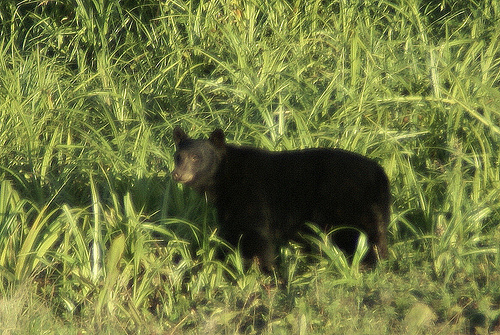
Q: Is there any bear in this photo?
A: Yes, there is a bear.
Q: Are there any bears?
A: Yes, there is a bear.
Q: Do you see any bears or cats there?
A: Yes, there is a bear.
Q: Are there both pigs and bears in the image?
A: No, there is a bear but no pigs.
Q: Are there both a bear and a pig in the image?
A: No, there is a bear but no pigs.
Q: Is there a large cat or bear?
A: Yes, there is a large bear.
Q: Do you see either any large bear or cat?
A: Yes, there is a large bear.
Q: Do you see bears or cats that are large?
A: Yes, the bear is large.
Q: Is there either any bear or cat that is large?
A: Yes, the bear is large.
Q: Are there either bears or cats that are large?
A: Yes, the bear is large.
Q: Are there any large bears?
A: Yes, there is a large bear.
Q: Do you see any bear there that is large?
A: Yes, there is a large bear.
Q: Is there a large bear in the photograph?
A: Yes, there is a large bear.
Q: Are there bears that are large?
A: Yes, there is a bear that is large.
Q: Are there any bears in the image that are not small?
A: Yes, there is a large bear.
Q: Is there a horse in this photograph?
A: No, there are no horses.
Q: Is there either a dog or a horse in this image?
A: No, there are no horses or dogs.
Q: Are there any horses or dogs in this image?
A: No, there are no horses or dogs.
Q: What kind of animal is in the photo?
A: The animal is a bear.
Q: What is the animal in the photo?
A: The animal is a bear.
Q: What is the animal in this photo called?
A: The animal is a bear.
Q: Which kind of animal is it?
A: The animal is a bear.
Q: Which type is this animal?
A: This is a bear.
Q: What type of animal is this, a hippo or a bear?
A: This is a bear.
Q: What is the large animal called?
A: The animal is a bear.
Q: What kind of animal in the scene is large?
A: The animal is a bear.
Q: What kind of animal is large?
A: The animal is a bear.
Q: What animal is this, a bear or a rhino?
A: This is a bear.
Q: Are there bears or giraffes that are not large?
A: No, there is a bear but it is large.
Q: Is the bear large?
A: Yes, the bear is large.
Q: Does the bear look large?
A: Yes, the bear is large.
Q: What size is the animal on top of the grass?
A: The bear is large.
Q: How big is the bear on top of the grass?
A: The bear is large.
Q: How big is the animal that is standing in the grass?
A: The bear is large.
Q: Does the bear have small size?
A: No, the bear is large.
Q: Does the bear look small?
A: No, the bear is large.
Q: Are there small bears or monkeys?
A: No, there is a bear but it is large.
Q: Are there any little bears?
A: No, there is a bear but it is large.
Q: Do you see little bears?
A: No, there is a bear but it is large.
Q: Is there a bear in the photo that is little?
A: No, there is a bear but it is large.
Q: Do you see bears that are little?
A: No, there is a bear but it is large.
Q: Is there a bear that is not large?
A: No, there is a bear but it is large.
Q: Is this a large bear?
A: Yes, this is a large bear.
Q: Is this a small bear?
A: No, this is a large bear.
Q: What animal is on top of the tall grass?
A: The bear is on top of the grass.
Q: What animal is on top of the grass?
A: The bear is on top of the grass.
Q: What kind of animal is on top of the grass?
A: The animal is a bear.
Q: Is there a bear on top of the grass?
A: Yes, there is a bear on top of the grass.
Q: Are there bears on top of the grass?
A: Yes, there is a bear on top of the grass.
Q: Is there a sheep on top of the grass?
A: No, there is a bear on top of the grass.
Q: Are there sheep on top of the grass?
A: No, there is a bear on top of the grass.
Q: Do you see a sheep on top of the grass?
A: No, there is a bear on top of the grass.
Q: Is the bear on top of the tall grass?
A: Yes, the bear is on top of the grass.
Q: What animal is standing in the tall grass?
A: The bear is standing in the grass.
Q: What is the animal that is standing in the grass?
A: The animal is a bear.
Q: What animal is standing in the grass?
A: The animal is a bear.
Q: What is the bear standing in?
A: The bear is standing in the grass.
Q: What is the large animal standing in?
A: The bear is standing in the grass.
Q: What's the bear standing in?
A: The bear is standing in the grass.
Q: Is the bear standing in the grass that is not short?
A: Yes, the bear is standing in the grass.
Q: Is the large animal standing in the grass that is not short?
A: Yes, the bear is standing in the grass.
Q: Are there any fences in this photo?
A: No, there are no fences.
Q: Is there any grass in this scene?
A: Yes, there is grass.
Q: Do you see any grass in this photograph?
A: Yes, there is grass.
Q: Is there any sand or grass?
A: Yes, there is grass.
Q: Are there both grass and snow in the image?
A: No, there is grass but no snow.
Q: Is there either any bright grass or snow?
A: Yes, there is bright grass.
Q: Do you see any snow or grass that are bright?
A: Yes, the grass is bright.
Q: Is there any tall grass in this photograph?
A: Yes, there is tall grass.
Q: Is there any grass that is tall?
A: Yes, there is grass that is tall.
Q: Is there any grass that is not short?
A: Yes, there is tall grass.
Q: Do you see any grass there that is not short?
A: Yes, there is tall grass.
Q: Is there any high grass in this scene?
A: Yes, there is high grass.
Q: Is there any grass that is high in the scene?
A: Yes, there is high grass.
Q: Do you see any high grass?
A: Yes, there is high grass.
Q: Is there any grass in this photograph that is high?
A: Yes, there is grass that is high.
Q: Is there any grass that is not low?
A: Yes, there is high grass.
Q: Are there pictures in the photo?
A: No, there are no pictures.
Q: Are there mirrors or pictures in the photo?
A: No, there are no pictures or mirrors.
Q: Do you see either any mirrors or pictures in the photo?
A: No, there are no pictures or mirrors.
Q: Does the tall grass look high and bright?
A: Yes, the grass is high and bright.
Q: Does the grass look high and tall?
A: Yes, the grass is high and tall.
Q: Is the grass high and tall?
A: Yes, the grass is high and tall.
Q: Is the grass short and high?
A: No, the grass is high but tall.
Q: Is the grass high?
A: Yes, the grass is high.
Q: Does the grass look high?
A: Yes, the grass is high.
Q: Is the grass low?
A: No, the grass is high.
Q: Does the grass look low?
A: No, the grass is high.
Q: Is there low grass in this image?
A: No, there is grass but it is high.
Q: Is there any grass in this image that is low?
A: No, there is grass but it is high.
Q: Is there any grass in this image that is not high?
A: No, there is grass but it is high.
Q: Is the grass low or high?
A: The grass is high.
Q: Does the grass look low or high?
A: The grass is high.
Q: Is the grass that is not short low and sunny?
A: No, the grass is sunny but high.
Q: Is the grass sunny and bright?
A: Yes, the grass is sunny and bright.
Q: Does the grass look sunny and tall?
A: Yes, the grass is sunny and tall.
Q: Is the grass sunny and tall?
A: Yes, the grass is sunny and tall.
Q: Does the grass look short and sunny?
A: No, the grass is sunny but tall.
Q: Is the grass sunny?
A: Yes, the grass is sunny.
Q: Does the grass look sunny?
A: Yes, the grass is sunny.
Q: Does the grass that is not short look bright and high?
A: Yes, the grass is bright and high.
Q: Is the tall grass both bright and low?
A: No, the grass is bright but high.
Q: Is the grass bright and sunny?
A: Yes, the grass is bright and sunny.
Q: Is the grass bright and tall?
A: Yes, the grass is bright and tall.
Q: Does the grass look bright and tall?
A: Yes, the grass is bright and tall.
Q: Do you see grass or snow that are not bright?
A: No, there is grass but it is bright.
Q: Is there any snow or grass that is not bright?
A: No, there is grass but it is bright.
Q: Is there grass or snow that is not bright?
A: No, there is grass but it is bright.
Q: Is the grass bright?
A: Yes, the grass is bright.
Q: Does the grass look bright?
A: Yes, the grass is bright.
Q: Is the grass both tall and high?
A: Yes, the grass is tall and high.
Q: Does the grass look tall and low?
A: No, the grass is tall but high.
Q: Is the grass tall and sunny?
A: Yes, the grass is tall and sunny.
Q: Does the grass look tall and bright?
A: Yes, the grass is tall and bright.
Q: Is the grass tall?
A: Yes, the grass is tall.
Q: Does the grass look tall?
A: Yes, the grass is tall.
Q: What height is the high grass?
A: The grass is tall.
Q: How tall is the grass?
A: The grass is tall.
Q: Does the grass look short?
A: No, the grass is tall.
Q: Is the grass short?
A: No, the grass is tall.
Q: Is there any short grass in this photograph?
A: No, there is grass but it is tall.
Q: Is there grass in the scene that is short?
A: No, there is grass but it is tall.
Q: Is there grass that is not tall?
A: No, there is grass but it is tall.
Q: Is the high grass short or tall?
A: The grass is tall.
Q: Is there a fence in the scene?
A: No, there are no fences.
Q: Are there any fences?
A: No, there are no fences.